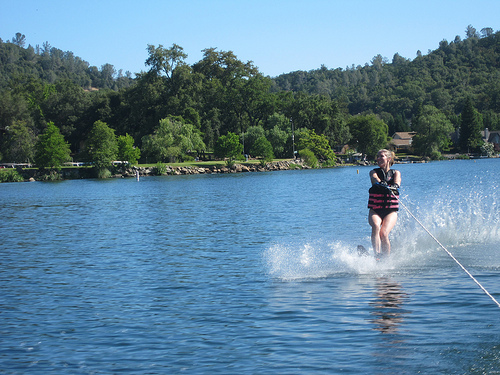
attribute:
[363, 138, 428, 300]
woman — water skiing, blonde, making splashes, smiling, outdoors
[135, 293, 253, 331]
lake — placid, blue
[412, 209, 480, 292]
tether line — for water skiing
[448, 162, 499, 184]
water — splashing, blue, large body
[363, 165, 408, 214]
life vest — striped, red, black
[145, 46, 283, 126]
trees — tall, green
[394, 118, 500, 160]
houses — in background